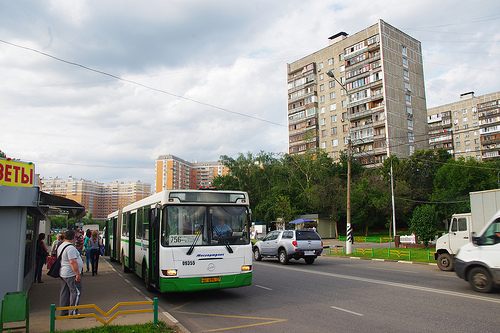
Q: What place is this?
A: It is a city.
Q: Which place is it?
A: It is a city.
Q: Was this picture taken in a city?
A: Yes, it was taken in a city.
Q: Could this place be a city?
A: Yes, it is a city.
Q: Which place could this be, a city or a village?
A: It is a city.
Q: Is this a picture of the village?
A: No, the picture is showing the city.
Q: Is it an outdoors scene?
A: Yes, it is outdoors.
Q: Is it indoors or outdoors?
A: It is outdoors.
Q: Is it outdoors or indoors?
A: It is outdoors.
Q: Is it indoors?
A: No, it is outdoors.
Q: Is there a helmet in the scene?
A: No, there are no helmets.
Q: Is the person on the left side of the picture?
A: Yes, the person is on the left of the image.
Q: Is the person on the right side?
A: No, the person is on the left of the image.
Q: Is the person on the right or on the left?
A: The person is on the left of the image.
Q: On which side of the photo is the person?
A: The person is on the left of the image.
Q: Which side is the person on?
A: The person is on the left of the image.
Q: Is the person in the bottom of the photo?
A: Yes, the person is in the bottom of the image.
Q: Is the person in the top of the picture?
A: No, the person is in the bottom of the image.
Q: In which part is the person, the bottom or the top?
A: The person is in the bottom of the image.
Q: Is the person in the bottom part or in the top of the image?
A: The person is in the bottom of the image.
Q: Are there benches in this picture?
A: No, there are no benches.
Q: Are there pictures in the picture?
A: No, there are no pictures.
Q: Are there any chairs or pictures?
A: No, there are no pictures or chairs.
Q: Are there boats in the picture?
A: No, there are no boats.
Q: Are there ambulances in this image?
A: No, there are no ambulances.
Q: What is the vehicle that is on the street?
A: The vehicle is a car.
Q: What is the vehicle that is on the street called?
A: The vehicle is a car.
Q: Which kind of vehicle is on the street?
A: The vehicle is a car.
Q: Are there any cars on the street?
A: Yes, there is a car on the street.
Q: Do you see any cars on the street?
A: Yes, there is a car on the street.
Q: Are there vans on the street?
A: No, there is a car on the street.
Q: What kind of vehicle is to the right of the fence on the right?
A: The vehicle is a car.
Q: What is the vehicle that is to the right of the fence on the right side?
A: The vehicle is a car.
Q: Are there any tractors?
A: No, there are no tractors.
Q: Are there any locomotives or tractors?
A: No, there are no tractors or locomotives.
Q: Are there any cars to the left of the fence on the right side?
A: Yes, there is a car to the left of the fence.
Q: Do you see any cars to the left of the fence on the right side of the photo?
A: Yes, there is a car to the left of the fence.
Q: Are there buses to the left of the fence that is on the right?
A: No, there is a car to the left of the fence.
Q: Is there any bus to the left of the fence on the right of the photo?
A: No, there is a car to the left of the fence.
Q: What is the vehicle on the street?
A: The vehicle is a car.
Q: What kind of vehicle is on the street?
A: The vehicle is a car.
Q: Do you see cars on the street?
A: Yes, there is a car on the street.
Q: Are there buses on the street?
A: No, there is a car on the street.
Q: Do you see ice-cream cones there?
A: No, there are no ice-cream cones.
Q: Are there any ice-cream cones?
A: No, there are no ice-cream cones.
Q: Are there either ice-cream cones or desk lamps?
A: No, there are no ice-cream cones or desk lamps.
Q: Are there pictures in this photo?
A: No, there are no pictures.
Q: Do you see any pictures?
A: No, there are no pictures.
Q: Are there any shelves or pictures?
A: No, there are no pictures or shelves.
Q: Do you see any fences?
A: Yes, there is a fence.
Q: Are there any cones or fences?
A: Yes, there is a fence.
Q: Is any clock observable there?
A: No, there are no clocks.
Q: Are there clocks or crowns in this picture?
A: No, there are no clocks or crowns.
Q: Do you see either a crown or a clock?
A: No, there are no clocks or crowns.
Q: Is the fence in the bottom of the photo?
A: Yes, the fence is in the bottom of the image.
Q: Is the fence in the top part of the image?
A: No, the fence is in the bottom of the image.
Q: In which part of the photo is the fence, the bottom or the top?
A: The fence is in the bottom of the image.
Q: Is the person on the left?
A: Yes, the person is on the left of the image.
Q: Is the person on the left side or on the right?
A: The person is on the left of the image.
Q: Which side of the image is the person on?
A: The person is on the left of the image.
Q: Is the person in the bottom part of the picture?
A: Yes, the person is in the bottom of the image.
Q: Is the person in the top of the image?
A: No, the person is in the bottom of the image.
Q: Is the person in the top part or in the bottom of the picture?
A: The person is in the bottom of the image.